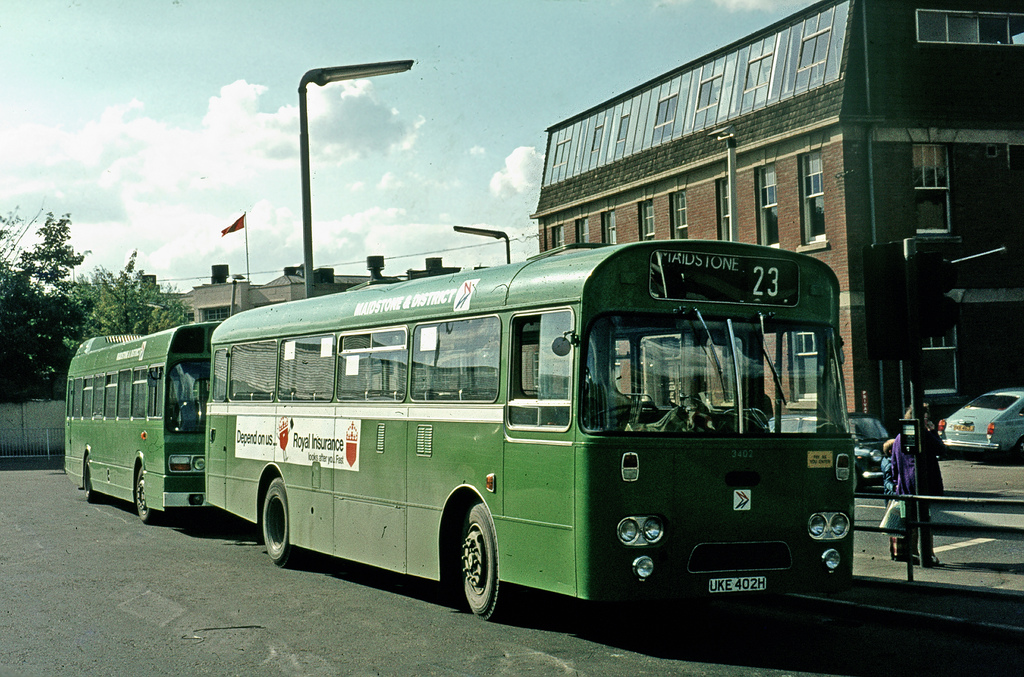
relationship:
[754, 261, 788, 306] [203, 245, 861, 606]
number 23 on bus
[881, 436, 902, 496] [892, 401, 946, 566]
child with person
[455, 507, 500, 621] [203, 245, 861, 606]
tire on bus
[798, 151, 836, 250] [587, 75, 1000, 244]
window on building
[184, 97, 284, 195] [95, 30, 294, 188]
clouds in sky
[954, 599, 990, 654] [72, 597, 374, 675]
crack in road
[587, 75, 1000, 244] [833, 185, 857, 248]
building has brick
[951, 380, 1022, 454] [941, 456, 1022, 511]
car in parking lot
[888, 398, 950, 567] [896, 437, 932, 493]
person wearing purple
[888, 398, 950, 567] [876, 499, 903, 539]
person holding bag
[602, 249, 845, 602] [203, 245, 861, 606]
flat-face of bus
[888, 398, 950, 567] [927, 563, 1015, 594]
people on sidewalk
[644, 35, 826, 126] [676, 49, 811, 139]
row of windows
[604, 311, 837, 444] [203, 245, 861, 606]
windshield on bus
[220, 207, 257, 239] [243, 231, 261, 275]
flag on flag pole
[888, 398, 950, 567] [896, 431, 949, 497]
person wearing jacket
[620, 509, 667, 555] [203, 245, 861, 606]
headlights on bus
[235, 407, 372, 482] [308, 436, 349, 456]
advertisement for insurance